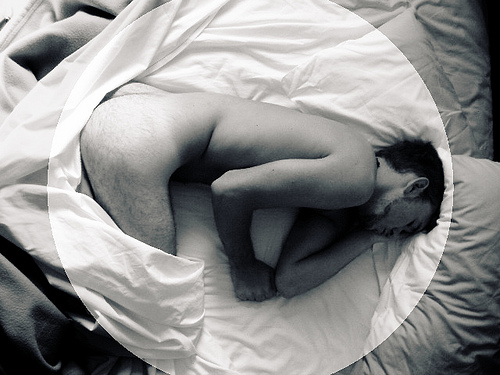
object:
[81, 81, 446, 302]
man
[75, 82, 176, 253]
tan line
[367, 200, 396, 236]
beard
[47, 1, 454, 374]
circle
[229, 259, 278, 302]
hand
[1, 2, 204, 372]
sheet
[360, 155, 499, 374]
pillow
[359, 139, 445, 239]
head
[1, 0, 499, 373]
bed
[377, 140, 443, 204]
hair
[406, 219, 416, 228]
eyes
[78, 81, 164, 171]
butt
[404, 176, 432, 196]
ear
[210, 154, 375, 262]
arm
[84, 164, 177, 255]
leg